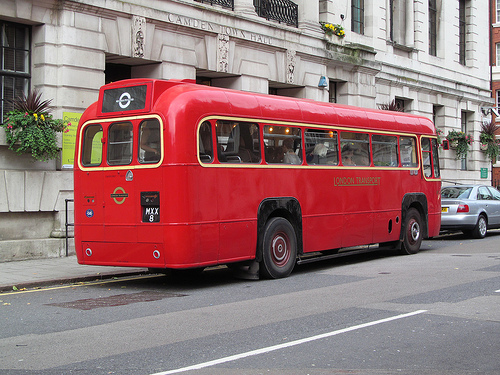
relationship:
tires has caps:
[401, 206, 428, 254] [407, 217, 420, 240]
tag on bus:
[137, 190, 162, 225] [70, 70, 442, 283]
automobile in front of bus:
[439, 177, 499, 243] [61, 59, 451, 294]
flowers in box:
[321, 21, 346, 38] [321, 22, 351, 48]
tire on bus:
[258, 216, 299, 279] [70, 70, 442, 283]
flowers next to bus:
[321, 21, 346, 38] [70, 70, 442, 283]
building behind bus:
[2, 0, 494, 234] [64, 77, 451, 259]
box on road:
[321, 22, 347, 38] [3, 231, 497, 372]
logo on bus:
[108, 186, 130, 203] [73, 78, 443, 280]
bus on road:
[70, 70, 442, 283] [3, 231, 497, 372]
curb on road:
[1, 270, 142, 289] [3, 231, 497, 372]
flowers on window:
[321, 21, 346, 38] [0, 18, 44, 126]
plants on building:
[445, 117, 492, 164] [26, 5, 497, 253]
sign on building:
[59, 109, 106, 166] [1, 0, 493, 265]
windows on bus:
[198, 117, 415, 167] [70, 70, 442, 283]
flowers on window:
[16, 96, 73, 175] [6, 25, 31, 97]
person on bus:
[138, 121, 158, 158] [70, 70, 442, 283]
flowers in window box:
[6, 96, 67, 160] [0, 20, 45, 148]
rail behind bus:
[57, 158, 86, 307] [64, 77, 451, 259]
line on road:
[73, 293, 444, 323] [3, 231, 497, 372]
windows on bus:
[198, 117, 415, 167] [164, 56, 394, 211]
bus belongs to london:
[70, 70, 442, 283] [333, 172, 394, 194]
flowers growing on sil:
[321, 21, 346, 38] [0, 121, 66, 217]